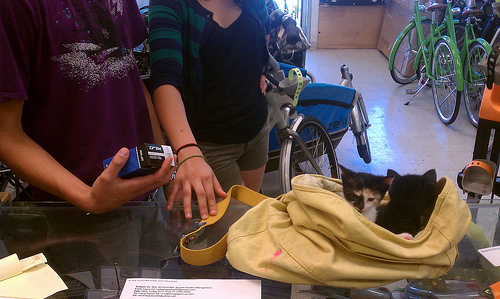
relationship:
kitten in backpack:
[340, 164, 383, 215] [293, 235, 457, 271]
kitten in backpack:
[392, 175, 433, 206] [293, 235, 457, 271]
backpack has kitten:
[293, 235, 457, 271] [340, 164, 383, 215]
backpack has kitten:
[293, 235, 457, 271] [392, 175, 433, 206]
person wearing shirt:
[10, 9, 166, 185] [55, 107, 76, 127]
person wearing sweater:
[166, 8, 271, 131] [158, 13, 188, 58]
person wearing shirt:
[166, 8, 271, 131] [243, 19, 253, 32]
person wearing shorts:
[166, 8, 271, 131] [211, 148, 267, 171]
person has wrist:
[166, 8, 271, 131] [181, 136, 195, 143]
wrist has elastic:
[181, 136, 195, 143] [178, 146, 193, 149]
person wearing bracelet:
[166, 8, 271, 131] [187, 158, 197, 159]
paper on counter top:
[14, 258, 54, 298] [12, 217, 168, 254]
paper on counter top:
[130, 284, 252, 298] [12, 217, 168, 254]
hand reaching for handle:
[177, 173, 217, 199] [177, 248, 210, 256]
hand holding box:
[100, 178, 145, 198] [138, 150, 165, 163]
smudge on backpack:
[270, 245, 289, 259] [293, 235, 457, 271]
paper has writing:
[130, 284, 252, 298] [165, 289, 189, 292]